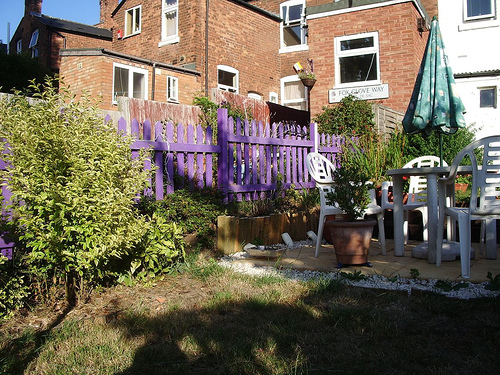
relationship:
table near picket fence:
[387, 165, 482, 262] [0, 108, 361, 260]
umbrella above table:
[402, 15, 467, 167] [387, 165, 482, 262]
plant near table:
[324, 163, 371, 221] [387, 165, 482, 262]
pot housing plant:
[326, 217, 378, 265] [324, 163, 371, 221]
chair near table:
[307, 151, 387, 257] [387, 165, 482, 262]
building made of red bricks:
[0, 0, 438, 124] [1, 1, 437, 122]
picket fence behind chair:
[0, 108, 361, 260] [307, 151, 387, 257]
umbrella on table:
[402, 15, 467, 167] [387, 165, 482, 262]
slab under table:
[228, 236, 498, 283] [387, 165, 482, 262]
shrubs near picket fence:
[0, 71, 494, 320] [0, 108, 361, 260]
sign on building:
[328, 82, 390, 104] [0, 0, 438, 124]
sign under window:
[328, 82, 390, 104] [333, 30, 381, 88]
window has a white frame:
[333, 30, 381, 88] [334, 30, 382, 89]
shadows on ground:
[1, 238, 500, 374] [0, 236, 499, 374]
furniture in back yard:
[308, 134, 498, 279] [0, 17, 499, 374]